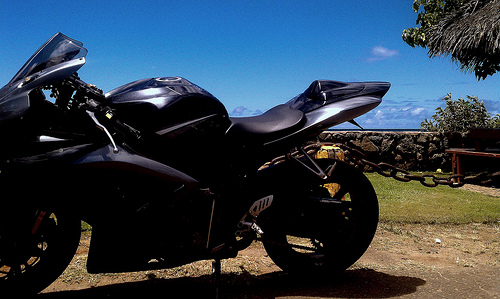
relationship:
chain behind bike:
[354, 135, 431, 187] [3, 22, 398, 297]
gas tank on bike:
[109, 72, 236, 153] [3, 22, 398, 297]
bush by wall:
[419, 92, 499, 128] [318, 129, 496, 171]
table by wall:
[448, 143, 496, 178] [338, 118, 443, 172]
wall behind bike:
[327, 125, 447, 171] [3, 22, 398, 297]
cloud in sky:
[373, 46, 397, 58] [4, 0, 497, 97]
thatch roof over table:
[427, 2, 499, 59] [446, 140, 499, 178]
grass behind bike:
[370, 174, 498, 223] [3, 22, 398, 297]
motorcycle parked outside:
[4, 31, 397, 296] [130, 27, 310, 81]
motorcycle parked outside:
[4, 31, 397, 296] [224, 11, 425, 116]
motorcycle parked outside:
[4, 31, 397, 296] [167, 49, 418, 152]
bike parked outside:
[3, 22, 398, 297] [197, 12, 413, 132]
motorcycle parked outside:
[4, 31, 397, 296] [138, 48, 433, 203]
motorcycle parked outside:
[4, 31, 397, 296] [120, 9, 418, 146]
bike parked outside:
[3, 22, 398, 297] [127, 8, 431, 139]